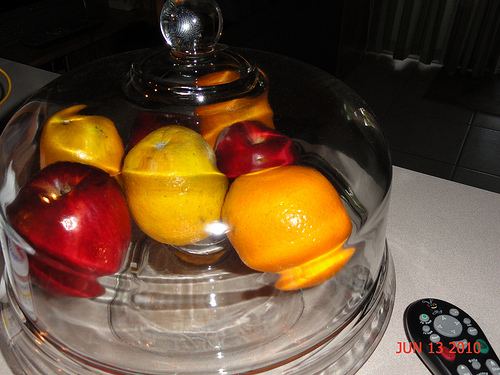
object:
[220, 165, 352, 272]
fruit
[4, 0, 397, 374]
bowl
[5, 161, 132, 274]
fruit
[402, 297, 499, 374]
remote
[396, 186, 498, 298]
table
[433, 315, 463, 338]
button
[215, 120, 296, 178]
apple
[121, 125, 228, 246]
orange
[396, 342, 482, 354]
date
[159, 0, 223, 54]
top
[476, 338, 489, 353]
button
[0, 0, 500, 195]
floor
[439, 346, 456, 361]
button